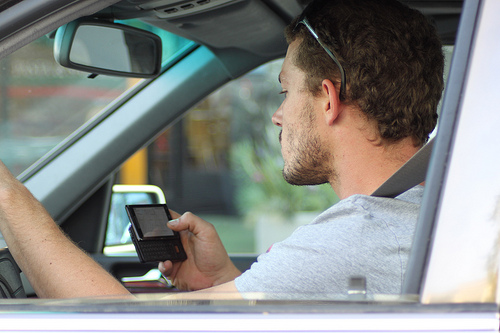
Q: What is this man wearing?
A: Sunglasses.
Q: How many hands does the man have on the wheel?
A: One.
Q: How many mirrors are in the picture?
A: Two.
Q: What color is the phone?
A: Black.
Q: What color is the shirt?
A: Grey.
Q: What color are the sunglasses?
A: Black.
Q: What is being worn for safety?
A: Seatbelt.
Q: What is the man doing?
A: Texting and driving.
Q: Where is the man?
A: In a car.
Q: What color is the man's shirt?
A: Grey.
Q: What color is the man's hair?
A: Brown.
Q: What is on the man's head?
A: Glasses.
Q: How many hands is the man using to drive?
A: 1.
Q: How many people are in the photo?
A: 1.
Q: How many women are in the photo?
A: 0.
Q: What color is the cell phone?
A: Black.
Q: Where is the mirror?
A: Front.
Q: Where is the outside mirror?
A: Right.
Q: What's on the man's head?
A: Glasses.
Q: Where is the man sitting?
A: Drivers Seat.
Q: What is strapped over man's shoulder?
A: Seatbelt.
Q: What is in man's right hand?
A: Phone.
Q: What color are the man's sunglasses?
A: Black.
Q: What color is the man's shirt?
A: Grey.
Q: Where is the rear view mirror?
A: Top front.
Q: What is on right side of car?
A: Side view mirror.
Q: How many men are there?
A: One.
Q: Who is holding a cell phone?
A: The man in the car.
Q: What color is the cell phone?
A: Black.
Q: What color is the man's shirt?
A: Gray.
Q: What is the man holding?
A: A cell phone.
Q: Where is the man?
A: In a car.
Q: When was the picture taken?
A: Daytime.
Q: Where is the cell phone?
A: In the man's hand.